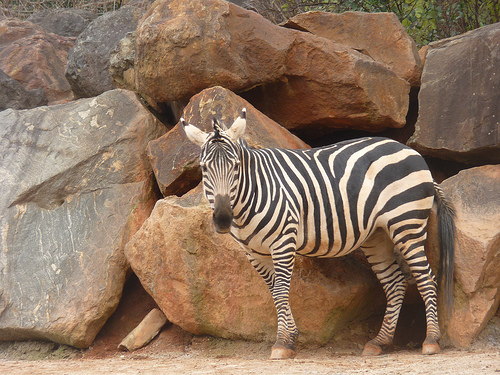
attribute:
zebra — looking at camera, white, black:
[180, 107, 458, 359]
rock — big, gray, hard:
[0, 87, 170, 350]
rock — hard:
[106, 1, 412, 137]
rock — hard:
[123, 178, 386, 347]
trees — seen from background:
[232, 1, 498, 47]